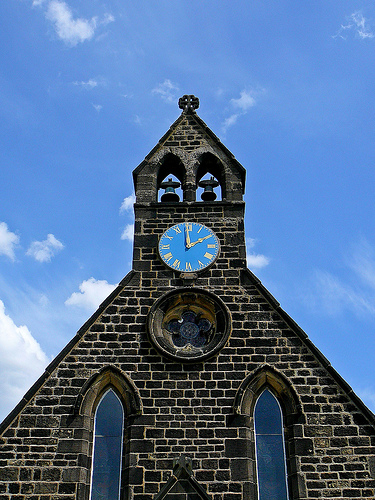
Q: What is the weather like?
A: It is clear.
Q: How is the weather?
A: It is clear.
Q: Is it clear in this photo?
A: Yes, it is clear.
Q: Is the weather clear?
A: Yes, it is clear.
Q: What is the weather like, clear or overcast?
A: It is clear.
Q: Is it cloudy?
A: No, it is clear.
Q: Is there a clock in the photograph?
A: Yes, there is a clock.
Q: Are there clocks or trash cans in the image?
A: Yes, there is a clock.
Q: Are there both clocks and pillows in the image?
A: No, there is a clock but no pillows.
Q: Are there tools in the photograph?
A: No, there are no tools.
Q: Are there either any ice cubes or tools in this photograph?
A: No, there are no tools or ice cubes.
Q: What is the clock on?
A: The clock is on the tower.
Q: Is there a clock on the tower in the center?
A: Yes, there is a clock on the tower.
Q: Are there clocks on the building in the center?
A: Yes, there is a clock on the tower.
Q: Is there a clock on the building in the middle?
A: Yes, there is a clock on the tower.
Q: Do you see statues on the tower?
A: No, there is a clock on the tower.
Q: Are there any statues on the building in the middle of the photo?
A: No, there is a clock on the tower.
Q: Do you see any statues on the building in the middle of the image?
A: No, there is a clock on the tower.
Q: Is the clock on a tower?
A: Yes, the clock is on a tower.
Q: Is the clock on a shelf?
A: No, the clock is on a tower.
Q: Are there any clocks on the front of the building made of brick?
A: Yes, there is a clock on the front of the building.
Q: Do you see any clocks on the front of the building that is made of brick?
A: Yes, there is a clock on the front of the building.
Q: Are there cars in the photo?
A: No, there are no cars.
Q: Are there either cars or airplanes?
A: No, there are no cars or airplanes.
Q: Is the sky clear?
A: Yes, the sky is clear.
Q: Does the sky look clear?
A: Yes, the sky is clear.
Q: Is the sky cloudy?
A: No, the sky is clear.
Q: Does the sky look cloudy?
A: No, the sky is clear.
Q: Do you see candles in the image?
A: No, there are no candles.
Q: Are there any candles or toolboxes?
A: No, there are no candles or toolboxes.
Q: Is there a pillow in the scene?
A: No, there are no pillows.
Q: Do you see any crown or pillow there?
A: No, there are no pillows or crowns.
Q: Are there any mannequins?
A: No, there are no mannequins.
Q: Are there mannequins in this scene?
A: No, there are no mannequins.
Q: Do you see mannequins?
A: No, there are no mannequins.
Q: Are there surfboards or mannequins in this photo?
A: No, there are no mannequins or surfboards.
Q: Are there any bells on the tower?
A: Yes, there is a bell on the tower.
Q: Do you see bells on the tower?
A: Yes, there is a bell on the tower.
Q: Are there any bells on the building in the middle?
A: Yes, there is a bell on the tower.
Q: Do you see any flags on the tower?
A: No, there is a bell on the tower.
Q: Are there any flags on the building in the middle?
A: No, there is a bell on the tower.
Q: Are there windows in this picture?
A: Yes, there is a window.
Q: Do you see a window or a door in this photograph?
A: Yes, there is a window.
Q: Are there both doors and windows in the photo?
A: No, there is a window but no doors.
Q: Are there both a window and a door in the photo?
A: No, there is a window but no doors.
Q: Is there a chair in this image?
A: No, there are no chairs.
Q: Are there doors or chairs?
A: No, there are no chairs or doors.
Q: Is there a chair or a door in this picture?
A: No, there are no chairs or doors.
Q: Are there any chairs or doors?
A: No, there are no chairs or doors.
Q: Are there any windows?
A: Yes, there is a window.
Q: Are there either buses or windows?
A: Yes, there is a window.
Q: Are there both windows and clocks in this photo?
A: Yes, there are both a window and a clock.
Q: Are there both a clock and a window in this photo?
A: Yes, there are both a window and a clock.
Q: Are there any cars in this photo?
A: No, there are no cars.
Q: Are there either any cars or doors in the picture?
A: No, there are no cars or doors.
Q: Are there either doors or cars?
A: No, there are no cars or doors.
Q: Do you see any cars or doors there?
A: No, there are no cars or doors.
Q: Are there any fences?
A: No, there are no fences.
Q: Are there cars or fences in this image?
A: No, there are no fences or cars.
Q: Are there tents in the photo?
A: No, there are no tents.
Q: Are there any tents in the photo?
A: No, there are no tents.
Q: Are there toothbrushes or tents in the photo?
A: No, there are no tents or toothbrushes.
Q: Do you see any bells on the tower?
A: Yes, there is a bell on the tower.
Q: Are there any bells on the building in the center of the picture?
A: Yes, there is a bell on the tower.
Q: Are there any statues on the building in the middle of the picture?
A: No, there is a bell on the tower.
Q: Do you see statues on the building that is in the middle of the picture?
A: No, there is a bell on the tower.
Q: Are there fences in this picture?
A: No, there are no fences.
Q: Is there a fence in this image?
A: No, there are no fences.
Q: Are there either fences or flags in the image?
A: No, there are no fences or flags.